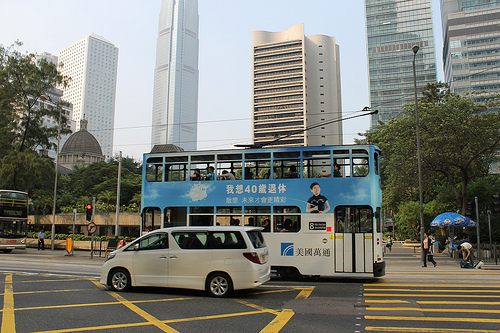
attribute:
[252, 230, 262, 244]
window — back window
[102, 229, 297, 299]
van — white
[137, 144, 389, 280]
double-decker bus — blue, white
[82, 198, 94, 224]
light — red, stop light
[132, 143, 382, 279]
bus — double decker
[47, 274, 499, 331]
stripes — painted, diagonal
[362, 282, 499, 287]
stripe — yellow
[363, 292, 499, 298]
stripe — yellow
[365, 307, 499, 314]
stripe — yellow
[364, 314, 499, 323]
stripe — yellow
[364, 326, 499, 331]
stripe — yellow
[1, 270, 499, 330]
street — yellow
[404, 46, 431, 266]
lightpole — metal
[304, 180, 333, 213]
man — picture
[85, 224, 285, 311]
van — white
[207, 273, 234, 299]
wheel — back wheel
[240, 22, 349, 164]
building — very tall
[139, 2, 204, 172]
building — very tall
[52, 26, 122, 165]
building — very tall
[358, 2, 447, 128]
building — very tall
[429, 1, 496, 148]
building — very tall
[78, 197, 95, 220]
light — red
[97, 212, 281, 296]
van — white